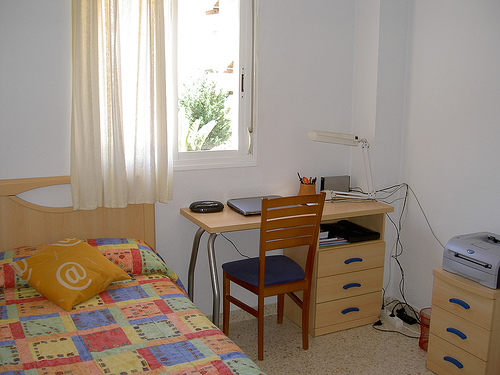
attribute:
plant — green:
[176, 63, 246, 173]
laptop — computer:
[221, 186, 303, 218]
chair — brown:
[199, 192, 357, 364]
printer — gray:
[426, 209, 498, 295]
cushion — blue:
[222, 251, 305, 288]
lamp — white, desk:
[307, 129, 375, 200]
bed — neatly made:
[4, 173, 256, 374]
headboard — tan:
[6, 167, 144, 250]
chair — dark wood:
[227, 199, 324, 341]